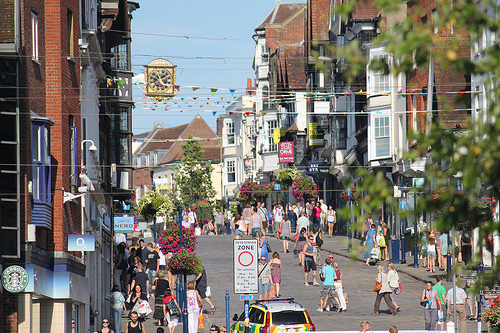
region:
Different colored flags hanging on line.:
[174, 82, 251, 97]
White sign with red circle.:
[229, 236, 269, 299]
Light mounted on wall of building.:
[76, 139, 105, 265]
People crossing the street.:
[305, 249, 413, 318]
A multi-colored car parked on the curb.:
[231, 295, 326, 332]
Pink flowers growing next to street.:
[157, 222, 204, 280]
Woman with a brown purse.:
[369, 273, 386, 295]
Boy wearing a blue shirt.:
[319, 264, 336, 289]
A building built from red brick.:
[12, 3, 93, 249]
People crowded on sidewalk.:
[113, 244, 174, 331]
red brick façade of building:
[41, 55, 74, 129]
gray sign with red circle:
[227, 239, 262, 306]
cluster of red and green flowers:
[158, 220, 210, 265]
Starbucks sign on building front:
[3, 257, 40, 299]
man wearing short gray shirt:
[300, 236, 323, 264]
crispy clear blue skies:
[144, 4, 256, 22]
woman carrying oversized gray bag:
[162, 289, 186, 319]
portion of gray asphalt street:
[200, 239, 224, 269]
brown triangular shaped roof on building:
[140, 114, 227, 174]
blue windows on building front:
[27, 102, 62, 227]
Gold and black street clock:
[133, 53, 183, 108]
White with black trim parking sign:
[228, 228, 263, 300]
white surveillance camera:
[62, 165, 97, 211]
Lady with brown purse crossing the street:
[371, 261, 395, 319]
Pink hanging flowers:
[158, 223, 198, 258]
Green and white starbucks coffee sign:
[1, 260, 32, 303]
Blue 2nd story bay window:
[28, 108, 58, 233]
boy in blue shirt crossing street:
[316, 253, 343, 315]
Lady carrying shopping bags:
[128, 282, 149, 318]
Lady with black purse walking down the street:
[418, 275, 440, 332]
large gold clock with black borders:
[142, 57, 182, 108]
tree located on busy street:
[164, 127, 227, 221]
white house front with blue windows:
[360, 50, 407, 167]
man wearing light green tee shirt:
[317, 258, 337, 289]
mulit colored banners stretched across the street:
[128, 72, 253, 125]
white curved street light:
[73, 130, 98, 237]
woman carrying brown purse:
[370, 266, 400, 307]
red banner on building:
[275, 130, 302, 166]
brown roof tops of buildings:
[135, 113, 233, 164]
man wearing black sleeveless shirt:
[123, 312, 146, 332]